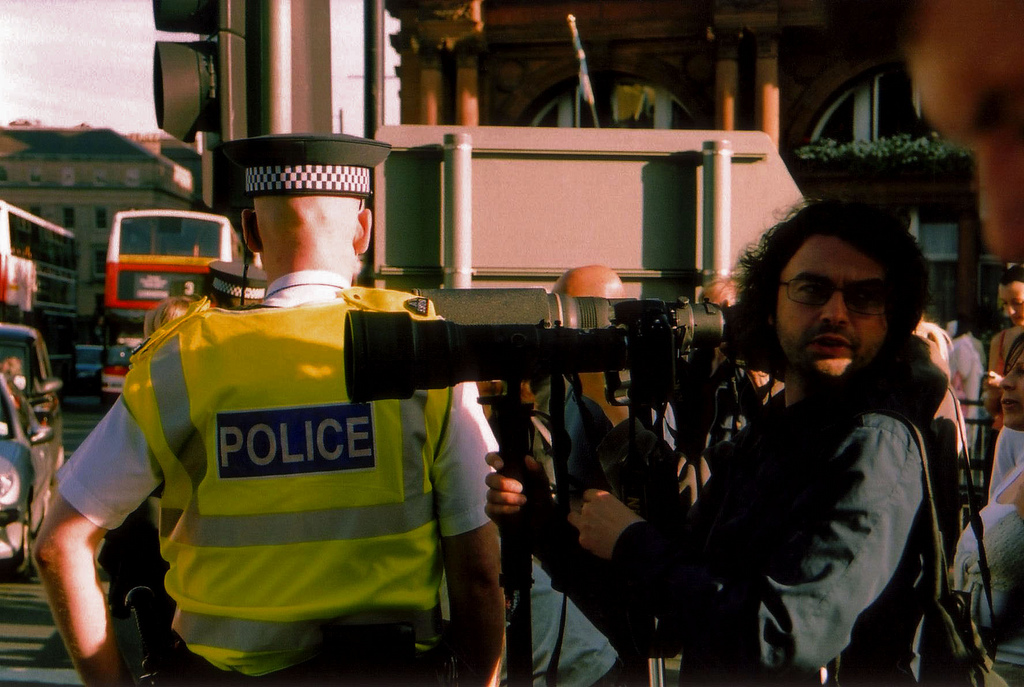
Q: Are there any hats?
A: Yes, there is a hat.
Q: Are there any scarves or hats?
A: Yes, there is a hat.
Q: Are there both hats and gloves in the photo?
A: No, there is a hat but no gloves.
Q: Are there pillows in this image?
A: No, there are no pillows.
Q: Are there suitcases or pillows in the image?
A: No, there are no pillows or suitcases.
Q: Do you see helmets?
A: No, there are no helmets.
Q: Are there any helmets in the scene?
A: No, there are no helmets.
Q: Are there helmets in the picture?
A: No, there are no helmets.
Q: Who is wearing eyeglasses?
A: The man is wearing eyeglasses.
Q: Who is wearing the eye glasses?
A: The man is wearing eyeglasses.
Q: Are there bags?
A: Yes, there is a bag.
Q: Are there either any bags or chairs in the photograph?
A: Yes, there is a bag.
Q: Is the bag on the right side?
A: Yes, the bag is on the right of the image.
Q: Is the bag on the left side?
A: No, the bag is on the right of the image.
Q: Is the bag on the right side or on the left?
A: The bag is on the right of the image.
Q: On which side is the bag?
A: The bag is on the right of the image.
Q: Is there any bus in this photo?
A: Yes, there is a bus.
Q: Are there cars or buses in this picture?
A: Yes, there is a bus.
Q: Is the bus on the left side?
A: Yes, the bus is on the left of the image.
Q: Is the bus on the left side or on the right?
A: The bus is on the left of the image.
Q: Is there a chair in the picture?
A: No, there are no chairs.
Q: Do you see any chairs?
A: No, there are no chairs.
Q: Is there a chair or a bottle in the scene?
A: No, there are no chairs or bottles.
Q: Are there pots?
A: Yes, there is a pot.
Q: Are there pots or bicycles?
A: Yes, there is a pot.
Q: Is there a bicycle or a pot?
A: Yes, there is a pot.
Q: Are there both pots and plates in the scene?
A: No, there is a pot but no plates.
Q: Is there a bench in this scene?
A: No, there are no benches.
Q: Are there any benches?
A: No, there are no benches.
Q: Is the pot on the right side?
A: Yes, the pot is on the right of the image.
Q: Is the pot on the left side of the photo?
A: No, the pot is on the right of the image.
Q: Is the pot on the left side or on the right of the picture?
A: The pot is on the right of the image.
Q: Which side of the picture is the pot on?
A: The pot is on the right of the image.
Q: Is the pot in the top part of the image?
A: Yes, the pot is in the top of the image.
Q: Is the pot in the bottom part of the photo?
A: No, the pot is in the top of the image.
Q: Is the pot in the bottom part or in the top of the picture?
A: The pot is in the top of the image.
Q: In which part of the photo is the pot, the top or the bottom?
A: The pot is in the top of the image.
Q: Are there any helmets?
A: No, there are no helmets.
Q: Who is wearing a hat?
A: The man is wearing a hat.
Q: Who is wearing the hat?
A: The man is wearing a hat.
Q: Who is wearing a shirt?
A: The man is wearing a shirt.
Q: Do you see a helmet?
A: No, there are no helmets.